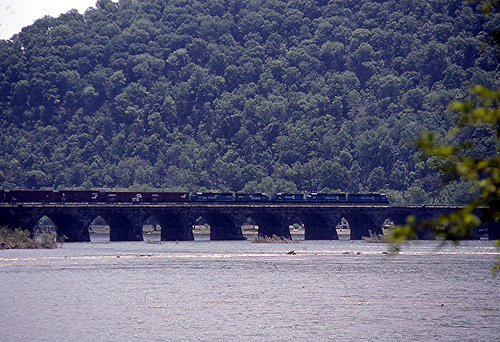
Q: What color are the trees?
A: Green.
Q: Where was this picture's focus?
A: A train bridge crossing.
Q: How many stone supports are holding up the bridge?
A: Nine.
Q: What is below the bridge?
A: Water.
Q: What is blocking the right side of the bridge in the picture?
A: A branch.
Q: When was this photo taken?
A: Day time.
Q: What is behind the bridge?
A: A beach.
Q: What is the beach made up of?
A: Sand.